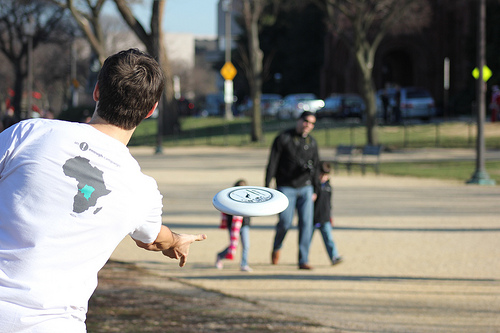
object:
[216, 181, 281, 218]
frisbee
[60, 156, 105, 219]
africa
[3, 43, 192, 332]
man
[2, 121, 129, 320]
shirt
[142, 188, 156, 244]
sleeve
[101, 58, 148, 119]
hair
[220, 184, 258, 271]
girl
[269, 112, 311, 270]
man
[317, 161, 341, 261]
boy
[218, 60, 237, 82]
sign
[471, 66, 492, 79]
sign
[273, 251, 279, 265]
shoe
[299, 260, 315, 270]
shoe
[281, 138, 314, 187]
jacket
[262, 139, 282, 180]
sleeve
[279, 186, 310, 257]
pants